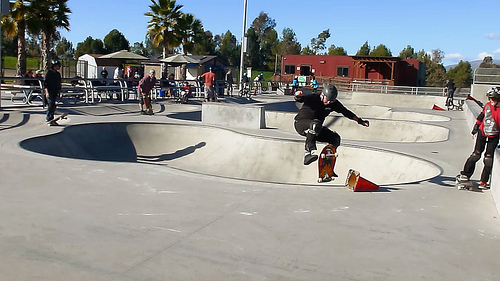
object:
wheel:
[320, 153, 325, 158]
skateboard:
[317, 144, 338, 183]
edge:
[45, 112, 65, 124]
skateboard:
[46, 110, 69, 125]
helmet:
[322, 84, 338, 100]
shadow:
[136, 142, 206, 162]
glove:
[471, 124, 480, 136]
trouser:
[294, 118, 341, 151]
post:
[237, 0, 247, 91]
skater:
[294, 84, 370, 165]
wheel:
[335, 152, 339, 157]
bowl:
[15, 121, 443, 186]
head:
[320, 85, 338, 106]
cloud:
[477, 51, 494, 60]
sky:
[9, 0, 500, 67]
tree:
[143, 0, 196, 78]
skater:
[42, 57, 62, 126]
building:
[281, 54, 427, 93]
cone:
[344, 169, 379, 192]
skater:
[457, 91, 500, 189]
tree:
[21, 0, 73, 80]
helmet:
[50, 59, 62, 70]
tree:
[1, 0, 41, 77]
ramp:
[201, 101, 266, 129]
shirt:
[476, 101, 500, 138]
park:
[0, 78, 497, 279]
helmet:
[485, 86, 499, 102]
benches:
[0, 78, 232, 106]